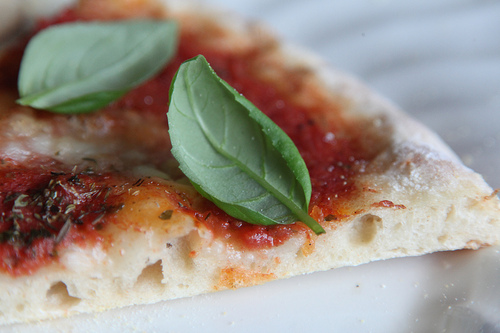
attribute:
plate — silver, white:
[1, 2, 494, 332]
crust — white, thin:
[1, 1, 499, 316]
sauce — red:
[0, 0, 368, 278]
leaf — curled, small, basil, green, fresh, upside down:
[166, 53, 324, 237]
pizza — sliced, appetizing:
[0, 4, 499, 316]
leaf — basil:
[17, 19, 181, 112]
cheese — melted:
[2, 103, 189, 195]